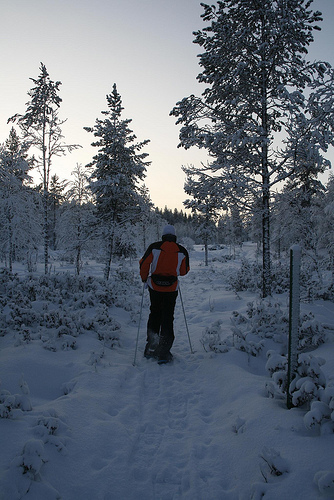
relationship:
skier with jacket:
[122, 213, 199, 376] [145, 242, 190, 288]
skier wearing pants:
[122, 213, 199, 376] [146, 294, 175, 350]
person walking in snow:
[134, 207, 196, 297] [204, 278, 229, 307]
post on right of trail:
[277, 230, 309, 415] [183, 380, 258, 434]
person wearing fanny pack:
[134, 207, 196, 297] [152, 273, 174, 287]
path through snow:
[96, 382, 198, 448] [204, 278, 229, 307]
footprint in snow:
[151, 390, 172, 413] [204, 278, 229, 307]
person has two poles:
[134, 207, 196, 297] [131, 327, 204, 357]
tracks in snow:
[183, 282, 208, 331] [204, 278, 229, 307]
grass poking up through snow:
[257, 453, 284, 477] [204, 278, 229, 307]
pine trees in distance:
[152, 208, 237, 232] [169, 205, 192, 216]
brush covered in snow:
[44, 299, 112, 343] [204, 278, 229, 307]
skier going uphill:
[122, 213, 199, 376] [174, 320, 186, 333]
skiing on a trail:
[113, 283, 201, 368] [183, 380, 258, 434]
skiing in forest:
[113, 283, 201, 368] [40, 169, 298, 230]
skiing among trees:
[113, 283, 201, 368] [30, 43, 291, 168]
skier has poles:
[122, 213, 199, 376] [131, 327, 204, 357]